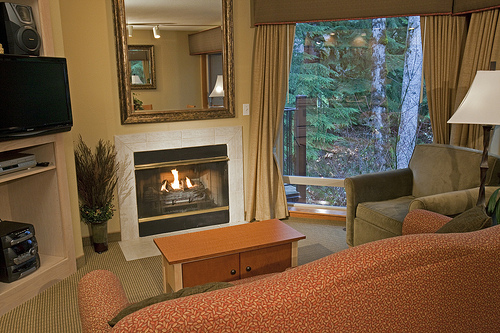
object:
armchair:
[345, 128, 491, 248]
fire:
[155, 164, 206, 203]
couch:
[409, 156, 436, 186]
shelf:
[29, 244, 78, 295]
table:
[146, 213, 306, 290]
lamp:
[445, 60, 499, 205]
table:
[447, 211, 499, 217]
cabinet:
[190, 259, 299, 289]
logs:
[145, 162, 225, 207]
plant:
[71, 130, 139, 261]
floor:
[313, 205, 347, 254]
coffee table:
[112, 211, 341, 293]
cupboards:
[178, 245, 306, 275]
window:
[282, 17, 433, 212]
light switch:
[242, 103, 250, 114]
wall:
[63, 4, 258, 229]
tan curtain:
[247, 25, 289, 215]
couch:
[75, 219, 498, 331]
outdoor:
[282, 18, 426, 210]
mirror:
[123, 15, 232, 125]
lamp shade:
[446, 70, 499, 124]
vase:
[69, 200, 123, 263]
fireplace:
[104, 116, 258, 246]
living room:
[6, 7, 480, 330]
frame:
[116, 56, 132, 107]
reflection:
[137, 4, 175, 112]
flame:
[168, 168, 183, 189]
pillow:
[430, 198, 498, 254]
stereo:
[3, 215, 42, 282]